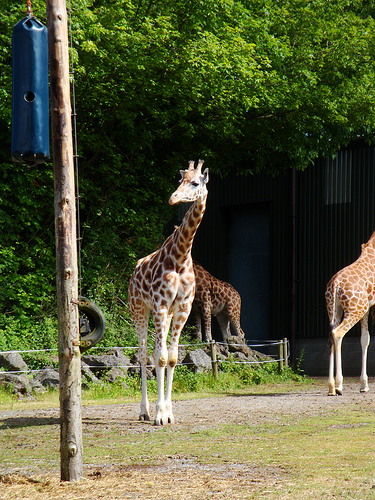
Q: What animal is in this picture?
A: Giraffes.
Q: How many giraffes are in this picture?
A: Three.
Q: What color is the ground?
A: Green and brown.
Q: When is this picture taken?
A: During the day.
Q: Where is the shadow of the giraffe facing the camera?
A: To the right of the giraffe and to the left of the picture.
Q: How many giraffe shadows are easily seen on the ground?
A: Two.